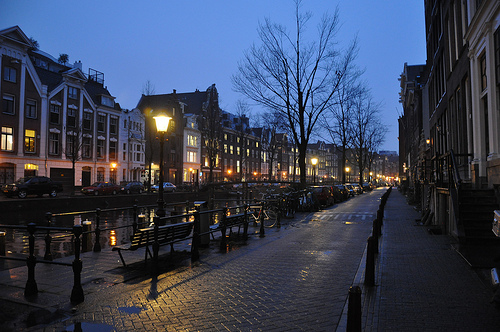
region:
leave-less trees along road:
[250, 5, 390, 216]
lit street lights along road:
[145, 100, 185, 145]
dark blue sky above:
[124, 12, 267, 66]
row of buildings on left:
[30, 41, 352, 179]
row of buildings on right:
[388, 20, 498, 200]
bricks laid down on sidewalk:
[175, 296, 320, 329]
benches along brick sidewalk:
[122, 228, 199, 245]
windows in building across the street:
[20, 125, 35, 152]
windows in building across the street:
[2, 125, 14, 147]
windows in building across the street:
[181, 135, 198, 147]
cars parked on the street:
[31, 165, 244, 204]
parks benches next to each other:
[99, 200, 305, 274]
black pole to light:
[149, 132, 169, 302]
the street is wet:
[12, 179, 168, 250]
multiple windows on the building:
[20, 115, 117, 162]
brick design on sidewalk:
[188, 257, 313, 319]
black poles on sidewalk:
[348, 174, 405, 316]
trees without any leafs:
[202, 5, 399, 198]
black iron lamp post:
[150, 109, 172, 299]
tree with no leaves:
[235, 6, 358, 208]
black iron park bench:
[120, 219, 195, 271]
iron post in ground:
[69, 226, 85, 306]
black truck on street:
[8, 175, 61, 198]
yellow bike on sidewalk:
[238, 199, 275, 229]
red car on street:
[83, 179, 120, 198]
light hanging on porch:
[426, 136, 431, 146]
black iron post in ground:
[346, 285, 362, 330]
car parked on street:
[155, 179, 177, 192]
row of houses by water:
[63, 84, 380, 178]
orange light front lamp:
[141, 111, 174, 134]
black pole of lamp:
[140, 138, 167, 301]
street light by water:
[134, 105, 176, 301]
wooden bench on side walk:
[108, 214, 209, 274]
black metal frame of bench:
[107, 246, 134, 273]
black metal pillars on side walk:
[340, 180, 412, 330]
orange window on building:
[0, 124, 42, 144]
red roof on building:
[17, 58, 72, 98]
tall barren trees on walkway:
[257, 9, 341, 165]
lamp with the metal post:
[153, 113, 178, 198]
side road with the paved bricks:
[281, 238, 319, 318]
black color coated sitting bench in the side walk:
[122, 221, 193, 257]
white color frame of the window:
[474, 46, 498, 143]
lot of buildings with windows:
[191, 99, 303, 168]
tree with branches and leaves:
[263, 30, 335, 150]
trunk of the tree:
[299, 167, 309, 191]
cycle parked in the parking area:
[260, 185, 283, 220]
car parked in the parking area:
[318, 181, 338, 203]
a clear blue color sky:
[118, 15, 213, 77]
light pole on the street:
[146, 110, 174, 285]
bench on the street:
[121, 225, 188, 252]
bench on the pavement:
[229, 211, 259, 231]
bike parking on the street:
[254, 194, 289, 262]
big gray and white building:
[10, 65, 113, 170]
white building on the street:
[126, 116, 141, 181]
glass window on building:
[1, 130, 6, 150]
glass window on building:
[1, 126, 11, 131]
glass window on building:
[23, 130, 37, 157]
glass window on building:
[0, 92, 16, 112]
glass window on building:
[1, 65, 20, 82]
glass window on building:
[67, 85, 77, 101]